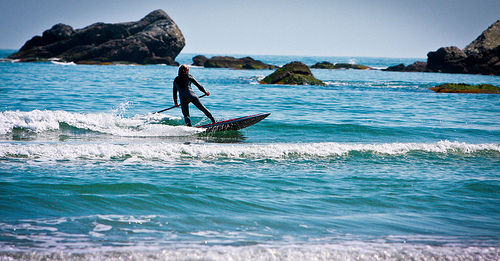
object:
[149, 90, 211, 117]
stick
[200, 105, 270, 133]
surfboard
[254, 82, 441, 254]
water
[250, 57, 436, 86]
island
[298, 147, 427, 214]
water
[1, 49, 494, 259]
water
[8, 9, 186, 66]
rock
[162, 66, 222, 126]
woman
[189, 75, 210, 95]
arm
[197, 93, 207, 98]
paddle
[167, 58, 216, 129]
person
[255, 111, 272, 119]
tip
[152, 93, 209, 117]
paddle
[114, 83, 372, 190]
water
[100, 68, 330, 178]
water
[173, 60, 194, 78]
hair